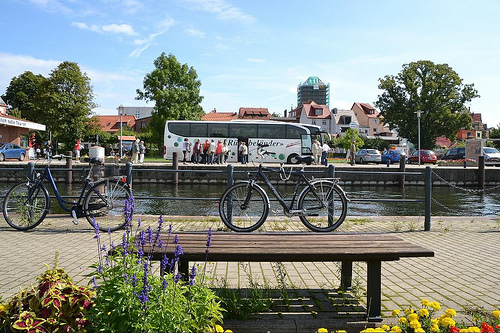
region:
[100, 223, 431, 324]
wooden bench without a back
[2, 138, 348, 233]
two bicycles parked next to the canal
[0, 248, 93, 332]
a patch of red and green coleus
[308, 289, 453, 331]
yellow African marigols planted near walkway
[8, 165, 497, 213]
a canal type waterway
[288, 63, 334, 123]
a tall building in the background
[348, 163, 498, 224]
metal railing with a chained section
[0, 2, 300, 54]
sunny blue skies with wispy clouds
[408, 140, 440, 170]
red car in the parking area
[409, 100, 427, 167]
tall lighting in the parking area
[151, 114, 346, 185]
A white colored tour bus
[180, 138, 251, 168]
A line of people waiting by a bus.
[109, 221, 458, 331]
A wooden bench.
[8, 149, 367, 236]
Bicycles leaned against a fence.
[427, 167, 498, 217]
Metal chains.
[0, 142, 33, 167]
A blue car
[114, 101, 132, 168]
A street light on a post.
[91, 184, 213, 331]
Purple flowers growing by the bench.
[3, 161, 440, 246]
A small dark colored fence.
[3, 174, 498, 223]
A river.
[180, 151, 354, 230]
bike leaning on green post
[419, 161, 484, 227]
black chains on posts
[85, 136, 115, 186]
white and brown object in water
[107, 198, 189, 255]
beautiful purple on the stalks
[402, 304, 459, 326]
small yellow flowers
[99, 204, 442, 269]
wide brown wooden seat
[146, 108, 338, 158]
large white passenger bus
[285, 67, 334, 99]
tall green square building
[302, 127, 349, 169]
people getting on the bus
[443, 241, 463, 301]
soft pink tiles on the ground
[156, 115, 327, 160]
Parked white bus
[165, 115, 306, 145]
Passenger window on right side of bus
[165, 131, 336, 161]
People standing outside of bus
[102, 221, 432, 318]
Deck to park bicycles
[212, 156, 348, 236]
Black bicycle on wood deck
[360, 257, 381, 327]
Front left leg of wood deck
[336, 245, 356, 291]
Back left leg of wood deck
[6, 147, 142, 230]
Black bicycle in front of bicycle on wood deck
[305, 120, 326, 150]
Front windshield of white bus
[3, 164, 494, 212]
Canal running inbetween platforms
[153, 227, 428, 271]
A wooden bench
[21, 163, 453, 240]
Two bikes chained against a metal bar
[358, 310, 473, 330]
Yellow flowers planted here.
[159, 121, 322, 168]
People standing in front of a white bus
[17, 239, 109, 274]
the ground has a tiled surface.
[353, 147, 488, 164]
Cars are parked in this area.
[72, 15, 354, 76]
The sky has blue with bits of white clouds.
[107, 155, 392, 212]
A flowing river surround by a man-made border.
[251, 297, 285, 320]
Green weeds poke between the tiles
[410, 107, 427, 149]
A lamp post standing right above the parked cars.